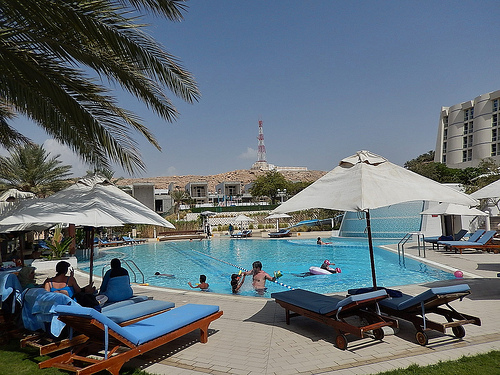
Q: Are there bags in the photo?
A: No, there are no bags.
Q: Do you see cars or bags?
A: No, there are no bags or cars.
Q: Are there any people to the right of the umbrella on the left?
A: Yes, there is a person to the right of the umbrella.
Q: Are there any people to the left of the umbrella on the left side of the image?
A: No, the person is to the right of the umbrella.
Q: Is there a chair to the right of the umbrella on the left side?
A: No, there is a person to the right of the umbrella.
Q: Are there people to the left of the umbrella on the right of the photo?
A: Yes, there is a person to the left of the umbrella.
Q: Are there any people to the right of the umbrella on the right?
A: No, the person is to the left of the umbrella.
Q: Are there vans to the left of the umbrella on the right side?
A: No, there is a person to the left of the umbrella.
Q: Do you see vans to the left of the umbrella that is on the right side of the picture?
A: No, there is a person to the left of the umbrella.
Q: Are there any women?
A: Yes, there is a woman.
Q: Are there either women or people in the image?
A: Yes, there is a woman.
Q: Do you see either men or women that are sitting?
A: Yes, the woman is sitting.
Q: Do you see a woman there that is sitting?
A: Yes, there is a woman that is sitting.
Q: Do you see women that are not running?
A: Yes, there is a woman that is sitting .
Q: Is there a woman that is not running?
A: Yes, there is a woman that is sitting.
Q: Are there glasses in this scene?
A: No, there are no glasses.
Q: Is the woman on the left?
A: Yes, the woman is on the left of the image.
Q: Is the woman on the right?
A: No, the woman is on the left of the image.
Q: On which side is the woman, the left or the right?
A: The woman is on the left of the image.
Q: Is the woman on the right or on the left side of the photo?
A: The woman is on the left of the image.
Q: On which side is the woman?
A: The woman is on the left of the image.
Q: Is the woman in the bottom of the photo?
A: Yes, the woman is in the bottom of the image.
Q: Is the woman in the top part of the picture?
A: No, the woman is in the bottom of the image.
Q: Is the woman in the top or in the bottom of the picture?
A: The woman is in the bottom of the image.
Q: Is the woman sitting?
A: Yes, the woman is sitting.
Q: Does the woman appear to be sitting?
A: Yes, the woman is sitting.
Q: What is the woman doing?
A: The woman is sitting.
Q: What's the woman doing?
A: The woman is sitting.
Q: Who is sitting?
A: The woman is sitting.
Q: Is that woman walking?
A: No, the woman is sitting.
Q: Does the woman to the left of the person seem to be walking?
A: No, the woman is sitting.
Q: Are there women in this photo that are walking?
A: No, there is a woman but she is sitting.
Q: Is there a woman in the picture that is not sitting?
A: No, there is a woman but she is sitting.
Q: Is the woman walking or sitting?
A: The woman is sitting.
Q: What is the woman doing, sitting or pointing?
A: The woman is sitting.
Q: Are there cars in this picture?
A: No, there are no cars.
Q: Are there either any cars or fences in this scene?
A: No, there are no cars or fences.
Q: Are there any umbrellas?
A: Yes, there is an umbrella.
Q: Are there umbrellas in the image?
A: Yes, there is an umbrella.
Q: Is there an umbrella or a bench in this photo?
A: Yes, there is an umbrella.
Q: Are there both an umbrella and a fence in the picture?
A: No, there is an umbrella but no fences.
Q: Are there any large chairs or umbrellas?
A: Yes, there is a large umbrella.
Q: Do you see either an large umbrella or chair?
A: Yes, there is a large umbrella.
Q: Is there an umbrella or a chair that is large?
A: Yes, the umbrella is large.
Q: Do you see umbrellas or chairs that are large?
A: Yes, the umbrella is large.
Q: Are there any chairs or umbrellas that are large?
A: Yes, the umbrella is large.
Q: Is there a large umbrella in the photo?
A: Yes, there is a large umbrella.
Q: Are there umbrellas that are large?
A: Yes, there is an umbrella that is large.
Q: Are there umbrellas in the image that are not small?
A: Yes, there is a large umbrella.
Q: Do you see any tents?
A: No, there are no tents.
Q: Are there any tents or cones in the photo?
A: No, there are no tents or cones.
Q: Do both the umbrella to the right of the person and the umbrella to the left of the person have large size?
A: Yes, both the umbrella and the umbrella are large.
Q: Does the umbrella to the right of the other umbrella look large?
A: Yes, the umbrella is large.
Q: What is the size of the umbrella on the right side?
A: The umbrella is large.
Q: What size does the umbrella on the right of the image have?
A: The umbrella has large size.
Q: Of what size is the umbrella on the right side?
A: The umbrella is large.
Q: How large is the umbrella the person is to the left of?
A: The umbrella is large.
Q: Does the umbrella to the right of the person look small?
A: No, the umbrella is large.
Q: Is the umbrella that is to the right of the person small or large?
A: The umbrella is large.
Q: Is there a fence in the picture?
A: No, there are no fences.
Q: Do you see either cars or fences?
A: No, there are no fences or cars.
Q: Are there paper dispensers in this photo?
A: No, there are no paper dispensers.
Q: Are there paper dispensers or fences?
A: No, there are no paper dispensers or fences.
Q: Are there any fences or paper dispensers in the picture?
A: No, there are no paper dispensers or fences.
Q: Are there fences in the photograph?
A: No, there are no fences.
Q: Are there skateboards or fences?
A: No, there are no fences or skateboards.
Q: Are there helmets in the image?
A: No, there are no helmets.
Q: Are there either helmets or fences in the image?
A: No, there are no helmets or fences.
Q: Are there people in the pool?
A: Yes, there is a person in the pool.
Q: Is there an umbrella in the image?
A: Yes, there is an umbrella.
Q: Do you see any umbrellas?
A: Yes, there is an umbrella.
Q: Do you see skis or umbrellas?
A: Yes, there is an umbrella.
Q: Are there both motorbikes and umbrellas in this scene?
A: No, there is an umbrella but no motorcycles.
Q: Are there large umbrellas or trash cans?
A: Yes, there is a large umbrella.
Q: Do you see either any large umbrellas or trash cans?
A: Yes, there is a large umbrella.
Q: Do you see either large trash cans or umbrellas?
A: Yes, there is a large umbrella.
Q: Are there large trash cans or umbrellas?
A: Yes, there is a large umbrella.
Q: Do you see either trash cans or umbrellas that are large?
A: Yes, the umbrella is large.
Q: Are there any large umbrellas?
A: Yes, there is a large umbrella.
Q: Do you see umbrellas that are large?
A: Yes, there is an umbrella that is large.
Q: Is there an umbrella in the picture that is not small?
A: Yes, there is a large umbrella.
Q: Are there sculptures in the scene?
A: No, there are no sculptures.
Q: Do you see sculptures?
A: No, there are no sculptures.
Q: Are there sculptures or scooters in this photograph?
A: No, there are no sculptures or scooters.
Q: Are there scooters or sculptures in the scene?
A: No, there are no sculptures or scooters.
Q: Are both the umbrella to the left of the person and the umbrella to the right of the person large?
A: Yes, both the umbrella and the umbrella are large.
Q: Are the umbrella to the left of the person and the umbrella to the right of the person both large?
A: Yes, both the umbrella and the umbrella are large.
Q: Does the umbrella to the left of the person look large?
A: Yes, the umbrella is large.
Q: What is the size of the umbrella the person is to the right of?
A: The umbrella is large.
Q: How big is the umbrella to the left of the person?
A: The umbrella is large.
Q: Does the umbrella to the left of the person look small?
A: No, the umbrella is large.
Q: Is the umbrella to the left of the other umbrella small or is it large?
A: The umbrella is large.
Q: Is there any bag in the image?
A: No, there are no bags.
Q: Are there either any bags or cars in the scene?
A: No, there are no bags or cars.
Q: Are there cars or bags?
A: No, there are no bags or cars.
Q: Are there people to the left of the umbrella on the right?
A: Yes, there is a person to the left of the umbrella.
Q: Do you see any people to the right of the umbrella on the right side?
A: No, the person is to the left of the umbrella.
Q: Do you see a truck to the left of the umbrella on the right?
A: No, there is a person to the left of the umbrella.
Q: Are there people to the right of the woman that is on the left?
A: Yes, there is a person to the right of the woman.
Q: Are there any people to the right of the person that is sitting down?
A: Yes, there is a person to the right of the woman.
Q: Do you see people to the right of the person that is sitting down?
A: Yes, there is a person to the right of the woman.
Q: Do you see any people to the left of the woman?
A: No, the person is to the right of the woman.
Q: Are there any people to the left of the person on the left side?
A: No, the person is to the right of the woman.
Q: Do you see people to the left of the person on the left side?
A: No, the person is to the right of the woman.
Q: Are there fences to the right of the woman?
A: No, there is a person to the right of the woman.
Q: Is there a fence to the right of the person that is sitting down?
A: No, there is a person to the right of the woman.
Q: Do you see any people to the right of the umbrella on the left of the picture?
A: Yes, there is a person to the right of the umbrella.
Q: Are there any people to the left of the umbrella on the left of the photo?
A: No, the person is to the right of the umbrella.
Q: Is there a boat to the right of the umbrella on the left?
A: No, there is a person to the right of the umbrella.